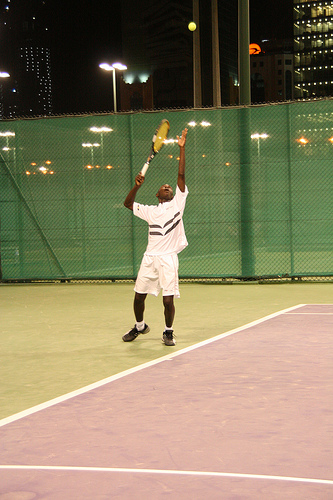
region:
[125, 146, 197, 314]
the man is looking up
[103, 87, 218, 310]
the man is looking up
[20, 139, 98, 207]
the net is green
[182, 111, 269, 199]
the net is green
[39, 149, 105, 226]
the net is green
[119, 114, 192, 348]
man hitting tennis ball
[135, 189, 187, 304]
man in black and white tennis outfit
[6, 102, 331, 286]
green netting around tennis court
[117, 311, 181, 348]
black shoes on player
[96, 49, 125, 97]
lights behind fence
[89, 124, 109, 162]
lights behind fence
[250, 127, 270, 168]
lights behind fence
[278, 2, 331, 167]
tall building with lights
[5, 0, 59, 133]
tall dark building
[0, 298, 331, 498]
man playing on pink tennis court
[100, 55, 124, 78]
The street lights are on.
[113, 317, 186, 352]
His shoes are black.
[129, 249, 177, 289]
His shorts are white.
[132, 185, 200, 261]
His shirt is white.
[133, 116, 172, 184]
The racket is white and yellow.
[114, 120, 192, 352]
He is holding the racket.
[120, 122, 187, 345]
He is swinging the racket.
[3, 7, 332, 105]
It is night outside.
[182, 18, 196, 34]
The ball is yellow.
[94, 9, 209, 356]
He is playing tennis.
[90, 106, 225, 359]
a man with a tennis racket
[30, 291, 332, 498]
white lines on the ground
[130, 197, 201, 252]
white shirt with black stripes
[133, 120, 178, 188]
a black and yellow racket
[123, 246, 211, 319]
white shorts on a man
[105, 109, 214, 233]
two arms stretching upward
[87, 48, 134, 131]
One light above the fence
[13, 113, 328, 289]
a green coating on the fence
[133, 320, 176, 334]
short white socks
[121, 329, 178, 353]
gray and black shoes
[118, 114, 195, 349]
a man serving a tennis ball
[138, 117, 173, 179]
a tennis racket used to play tennis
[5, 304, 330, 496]
red clay tennis court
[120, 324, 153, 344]
a mens laced athletic shoe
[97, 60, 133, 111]
city street light pole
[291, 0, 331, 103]
a building in the city at night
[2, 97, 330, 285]
a green mesh lined fence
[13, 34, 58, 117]
a lit up building in the city landscape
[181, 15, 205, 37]
a yellow tennis ball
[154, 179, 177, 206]
a mans face looking up